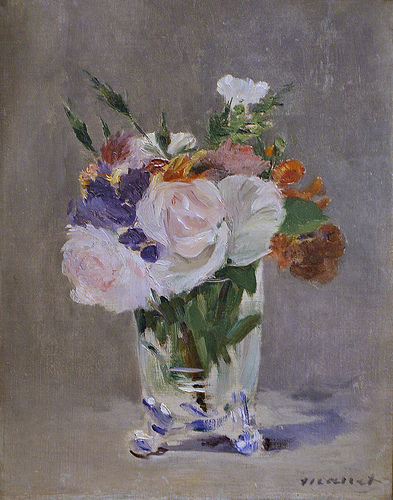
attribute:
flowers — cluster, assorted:
[61, 68, 348, 413]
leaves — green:
[60, 103, 96, 152]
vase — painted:
[136, 273, 258, 458]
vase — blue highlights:
[116, 258, 269, 456]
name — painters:
[295, 471, 387, 498]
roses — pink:
[133, 180, 229, 299]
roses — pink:
[58, 224, 155, 313]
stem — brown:
[172, 322, 213, 435]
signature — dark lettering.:
[299, 471, 383, 486]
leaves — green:
[194, 299, 242, 348]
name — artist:
[299, 474, 379, 488]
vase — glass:
[119, 278, 263, 435]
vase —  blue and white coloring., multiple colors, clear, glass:
[121, 250, 274, 462]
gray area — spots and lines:
[0, 1, 391, 498]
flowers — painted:
[40, 41, 345, 348]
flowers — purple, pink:
[63, 163, 159, 262]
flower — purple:
[63, 161, 172, 266]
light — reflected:
[163, 357, 210, 402]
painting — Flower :
[7, 10, 354, 498]